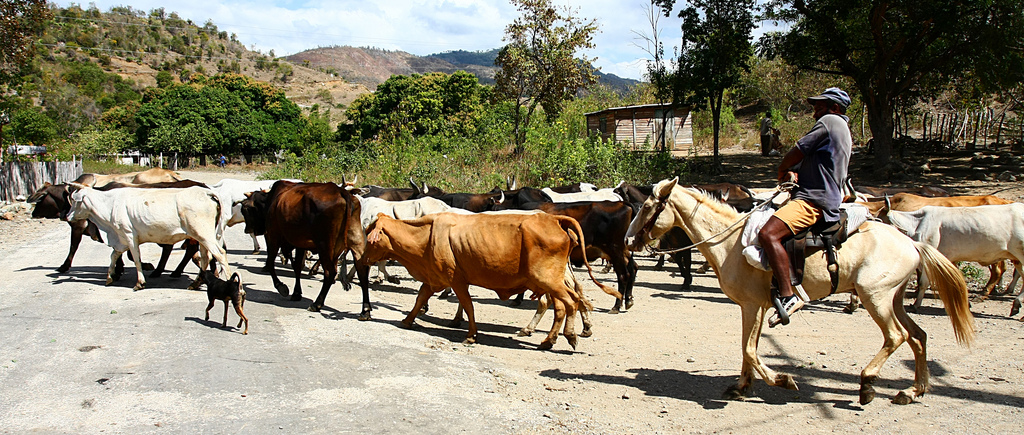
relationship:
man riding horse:
[762, 80, 855, 322] [729, 202, 943, 382]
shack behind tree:
[591, 95, 701, 156] [507, 57, 587, 150]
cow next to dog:
[57, 183, 241, 287] [176, 253, 252, 346]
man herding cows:
[762, 80, 855, 322] [27, 170, 1021, 402]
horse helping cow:
[623, 173, 976, 402] [29, 170, 1023, 346]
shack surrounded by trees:
[590, 95, 701, 156] [478, 2, 1017, 162]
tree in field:
[497, 4, 595, 141] [1, 153, 1017, 426]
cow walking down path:
[57, 183, 241, 287] [11, 170, 562, 432]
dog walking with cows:
[187, 263, 257, 333] [29, 170, 1015, 352]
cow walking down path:
[240, 175, 362, 301] [11, 170, 562, 432]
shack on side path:
[591, 95, 701, 156] [11, 170, 562, 432]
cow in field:
[878, 199, 1023, 312] [1, 153, 1017, 426]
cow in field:
[57, 183, 241, 287] [1, 153, 1017, 426]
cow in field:
[362, 209, 620, 350] [1, 153, 1017, 426]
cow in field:
[346, 194, 453, 216] [1, 153, 1017, 426]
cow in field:
[253, 181, 360, 302] [1, 153, 1017, 426]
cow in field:
[63, 181, 236, 292] [1, 153, 1017, 426]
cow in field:
[240, 179, 372, 294] [1, 153, 1017, 426]